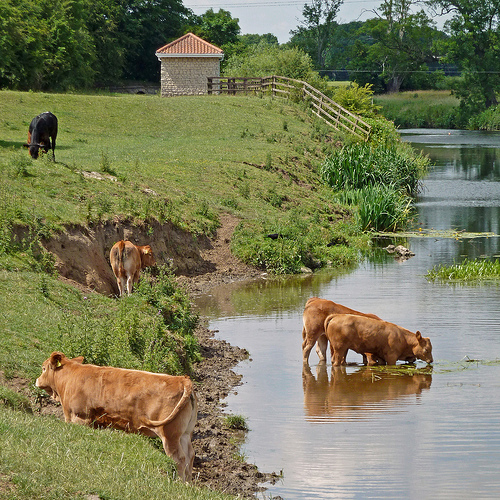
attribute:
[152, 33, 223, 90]
building — small, stone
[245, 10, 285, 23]
sky — light blue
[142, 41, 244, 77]
roof — orange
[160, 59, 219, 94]
wall — brown, brick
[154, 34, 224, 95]
house — small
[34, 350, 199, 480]
cow — brown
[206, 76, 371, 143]
fence — wooden, brown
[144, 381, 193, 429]
tail — brown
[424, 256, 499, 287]
grass — green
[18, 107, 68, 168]
cow — black, grazing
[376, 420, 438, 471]
patch — small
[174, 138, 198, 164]
patch — small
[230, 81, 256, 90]
section — small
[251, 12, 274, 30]
patch — small